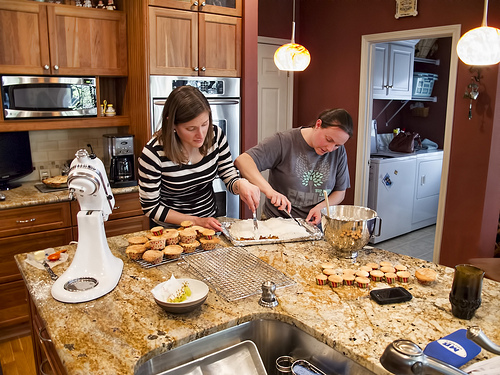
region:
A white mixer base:
[51, 148, 123, 307]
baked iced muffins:
[122, 219, 222, 264]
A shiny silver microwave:
[2, 73, 102, 120]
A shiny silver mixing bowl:
[319, 194, 384, 258]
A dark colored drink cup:
[447, 258, 487, 323]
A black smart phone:
[369, 282, 411, 311]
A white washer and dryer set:
[368, 133, 441, 244]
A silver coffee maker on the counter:
[103, 134, 138, 189]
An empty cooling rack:
[176, 243, 298, 303]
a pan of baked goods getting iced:
[218, 207, 320, 248]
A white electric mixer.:
[51, 148, 124, 302]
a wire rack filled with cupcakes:
[125, 220, 219, 263]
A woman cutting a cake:
[137, 85, 262, 227]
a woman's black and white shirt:
[135, 126, 237, 221]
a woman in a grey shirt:
[234, 108, 351, 218]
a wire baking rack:
[181, 248, 295, 302]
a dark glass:
[447, 263, 484, 320]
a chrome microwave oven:
[2, 75, 97, 120]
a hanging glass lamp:
[274, 3, 311, 76]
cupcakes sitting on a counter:
[316, 259, 411, 289]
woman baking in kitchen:
[150, 92, 239, 225]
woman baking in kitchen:
[278, 93, 364, 218]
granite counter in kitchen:
[49, 242, 182, 339]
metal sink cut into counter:
[138, 318, 321, 373]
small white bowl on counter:
[148, 263, 225, 323]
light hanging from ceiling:
[275, 37, 312, 79]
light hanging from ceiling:
[441, 16, 497, 50]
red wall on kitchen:
[434, 110, 478, 272]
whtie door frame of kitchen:
[360, 32, 373, 190]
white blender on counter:
[36, 151, 117, 299]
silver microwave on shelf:
[1, 73, 97, 119]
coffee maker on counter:
[100, 133, 138, 186]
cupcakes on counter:
[315, 256, 415, 286]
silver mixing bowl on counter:
[318, 190, 380, 259]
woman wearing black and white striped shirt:
[138, 83, 255, 235]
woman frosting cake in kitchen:
[235, 108, 352, 241]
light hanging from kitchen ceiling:
[273, 1, 312, 73]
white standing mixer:
[48, 149, 125, 304]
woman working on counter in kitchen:
[140, 83, 260, 247]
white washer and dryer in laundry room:
[369, 126, 441, 249]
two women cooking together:
[105, 51, 415, 276]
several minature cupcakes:
[310, 245, 415, 295]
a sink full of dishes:
[135, 331, 357, 372]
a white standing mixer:
[9, 117, 144, 323]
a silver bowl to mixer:
[312, 203, 396, 264]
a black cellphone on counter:
[366, 278, 421, 313]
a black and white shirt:
[127, 104, 251, 226]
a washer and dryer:
[368, 117, 472, 258]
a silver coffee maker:
[101, 124, 153, 186]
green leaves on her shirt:
[294, 161, 334, 205]